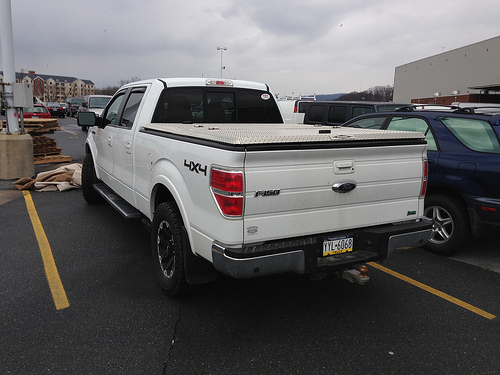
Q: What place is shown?
A: It is a street.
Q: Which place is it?
A: It is a street.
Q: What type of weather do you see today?
A: It is cloudy.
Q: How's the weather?
A: It is cloudy.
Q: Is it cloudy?
A: Yes, it is cloudy.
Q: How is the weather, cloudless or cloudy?
A: It is cloudy.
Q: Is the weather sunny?
A: No, it is cloudy.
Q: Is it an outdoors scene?
A: Yes, it is outdoors.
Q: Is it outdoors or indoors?
A: It is outdoors.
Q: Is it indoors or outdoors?
A: It is outdoors.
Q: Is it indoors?
A: No, it is outdoors.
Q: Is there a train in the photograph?
A: No, there are no trains.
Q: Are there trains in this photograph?
A: No, there are no trains.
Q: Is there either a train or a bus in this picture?
A: No, there are no trains or buses.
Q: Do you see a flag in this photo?
A: No, there are no flags.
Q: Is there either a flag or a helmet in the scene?
A: No, there are no flags or helmets.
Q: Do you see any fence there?
A: No, there are no fences.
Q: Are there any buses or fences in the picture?
A: No, there are no fences or buses.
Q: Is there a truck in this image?
A: Yes, there is a truck.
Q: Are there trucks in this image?
A: Yes, there is a truck.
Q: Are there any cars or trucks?
A: Yes, there is a truck.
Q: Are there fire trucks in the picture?
A: No, there are no fire trucks.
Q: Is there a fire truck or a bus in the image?
A: No, there are no fire trucks or buses.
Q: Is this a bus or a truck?
A: This is a truck.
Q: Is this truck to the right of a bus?
A: No, the truck is to the right of a car.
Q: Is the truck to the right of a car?
A: Yes, the truck is to the right of a car.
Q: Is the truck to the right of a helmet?
A: No, the truck is to the right of a car.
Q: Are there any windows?
A: Yes, there is a window.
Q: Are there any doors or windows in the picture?
A: Yes, there is a window.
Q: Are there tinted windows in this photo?
A: Yes, there is a tinted window.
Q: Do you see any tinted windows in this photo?
A: Yes, there is a tinted window.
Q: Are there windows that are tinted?
A: Yes, there is a window that is tinted.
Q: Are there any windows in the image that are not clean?
A: Yes, there is a tinted window.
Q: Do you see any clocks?
A: No, there are no clocks.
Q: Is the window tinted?
A: Yes, the window is tinted.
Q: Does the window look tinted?
A: Yes, the window is tinted.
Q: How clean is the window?
A: The window is tinted.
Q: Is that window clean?
A: No, the window is tinted.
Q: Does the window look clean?
A: No, the window is tinted.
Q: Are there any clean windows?
A: No, there is a window but it is tinted.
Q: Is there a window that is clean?
A: No, there is a window but it is tinted.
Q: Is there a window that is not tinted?
A: No, there is a window but it is tinted.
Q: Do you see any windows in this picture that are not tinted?
A: No, there is a window but it is tinted.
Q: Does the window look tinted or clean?
A: The window is tinted.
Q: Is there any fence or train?
A: No, there are no fences or trains.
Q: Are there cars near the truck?
A: Yes, there is a car near the truck.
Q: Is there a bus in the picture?
A: No, there are no buses.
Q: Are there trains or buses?
A: No, there are no buses or trains.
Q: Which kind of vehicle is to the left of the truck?
A: The vehicle is a car.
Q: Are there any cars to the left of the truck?
A: Yes, there is a car to the left of the truck.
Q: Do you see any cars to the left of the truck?
A: Yes, there is a car to the left of the truck.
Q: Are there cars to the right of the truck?
A: No, the car is to the left of the truck.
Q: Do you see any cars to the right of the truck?
A: No, the car is to the left of the truck.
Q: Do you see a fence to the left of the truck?
A: No, there is a car to the left of the truck.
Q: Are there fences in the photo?
A: No, there are no fences.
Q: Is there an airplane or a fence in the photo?
A: No, there are no fences or airplanes.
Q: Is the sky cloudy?
A: Yes, the sky is cloudy.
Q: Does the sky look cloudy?
A: Yes, the sky is cloudy.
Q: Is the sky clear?
A: No, the sky is cloudy.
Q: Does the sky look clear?
A: No, the sky is cloudy.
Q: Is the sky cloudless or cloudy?
A: The sky is cloudy.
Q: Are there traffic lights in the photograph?
A: No, there are no traffic lights.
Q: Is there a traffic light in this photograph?
A: No, there are no traffic lights.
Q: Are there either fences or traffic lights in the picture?
A: No, there are no traffic lights or fences.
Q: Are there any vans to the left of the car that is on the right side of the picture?
A: Yes, there is a van to the left of the car.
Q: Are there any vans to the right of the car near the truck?
A: No, the van is to the left of the car.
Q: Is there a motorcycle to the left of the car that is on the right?
A: No, there is a van to the left of the car.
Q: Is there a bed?
A: Yes, there is a bed.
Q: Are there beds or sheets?
A: Yes, there is a bed.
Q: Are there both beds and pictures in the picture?
A: No, there is a bed but no pictures.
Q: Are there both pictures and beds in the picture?
A: No, there is a bed but no pictures.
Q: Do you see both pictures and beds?
A: No, there is a bed but no pictures.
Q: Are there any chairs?
A: No, there are no chairs.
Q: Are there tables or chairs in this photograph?
A: No, there are no chairs or tables.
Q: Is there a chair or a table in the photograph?
A: No, there are no chairs or tables.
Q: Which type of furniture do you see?
A: The furniture is a bed.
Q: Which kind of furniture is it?
A: The piece of furniture is a bed.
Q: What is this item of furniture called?
A: This is a bed.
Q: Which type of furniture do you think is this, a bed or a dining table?
A: This is a bed.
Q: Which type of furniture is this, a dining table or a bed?
A: This is a bed.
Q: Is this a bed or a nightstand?
A: This is a bed.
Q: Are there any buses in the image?
A: No, there are no buses.